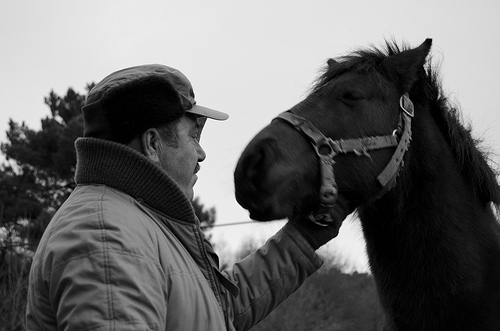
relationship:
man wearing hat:
[23, 62, 359, 331] [86, 67, 217, 129]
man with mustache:
[25, 62, 342, 329] [193, 163, 199, 172]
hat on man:
[81, 62, 230, 140] [25, 62, 342, 329]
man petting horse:
[25, 62, 342, 329] [247, 33, 494, 329]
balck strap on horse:
[280, 103, 422, 183] [231, 19, 484, 326]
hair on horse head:
[336, 46, 401, 83] [222, 30, 483, 247]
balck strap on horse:
[274, 94, 418, 218] [247, 33, 494, 329]